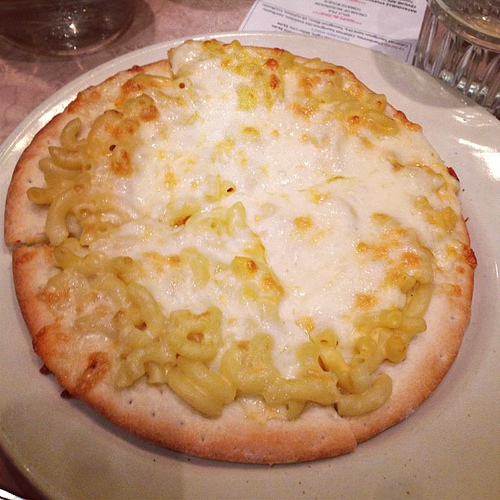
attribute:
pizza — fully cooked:
[11, 44, 473, 462]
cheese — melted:
[137, 265, 220, 312]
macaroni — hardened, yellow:
[2, 35, 469, 465]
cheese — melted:
[69, 42, 450, 380]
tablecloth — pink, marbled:
[1, 9, 294, 141]